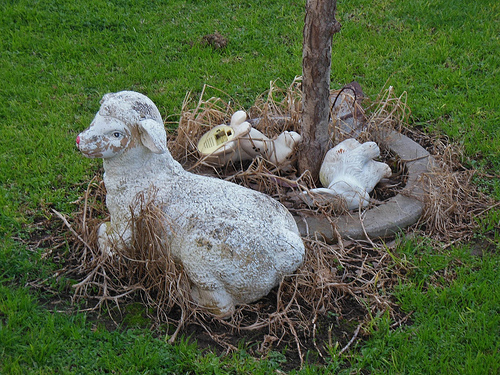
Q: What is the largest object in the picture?
A: A stone sheep.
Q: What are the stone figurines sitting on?
A: Dead plants.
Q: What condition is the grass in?
A: Short and green.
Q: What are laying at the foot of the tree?
A: Two stone rabbits.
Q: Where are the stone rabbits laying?
A: At the foot of the tree.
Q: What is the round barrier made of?
A: Stone.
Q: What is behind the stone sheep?
A: Two stone rabbits by a tree.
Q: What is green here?
A: Grass.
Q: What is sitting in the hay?
A: Figurine.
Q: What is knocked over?
A: The rabbit statues.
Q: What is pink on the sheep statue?
A: Nose.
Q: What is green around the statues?
A: The grass.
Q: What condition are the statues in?
A: Poor.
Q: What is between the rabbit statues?
A: Tree.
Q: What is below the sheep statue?
A: Dirt.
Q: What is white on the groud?
A: The statues.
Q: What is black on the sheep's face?
A: Eyes.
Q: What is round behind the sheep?
A: Pavement.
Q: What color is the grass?
A: Green.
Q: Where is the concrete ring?
A: Around the tree stump.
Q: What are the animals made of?
A: Resin and concrete.